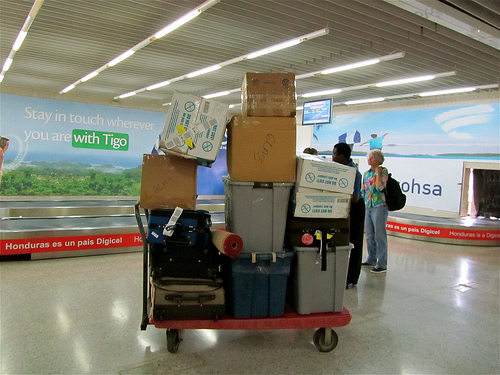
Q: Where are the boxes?
A: On the luggage cart.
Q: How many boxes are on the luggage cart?
A: 6.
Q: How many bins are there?
A: 3.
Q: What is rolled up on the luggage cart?
A: Rug.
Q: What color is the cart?
A: Red.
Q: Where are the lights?
A: On the ceiling.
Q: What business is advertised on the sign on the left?
A: Tigo.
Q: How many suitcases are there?
A: 3.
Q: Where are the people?
A: Behind the cart.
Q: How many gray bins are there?
A: 2.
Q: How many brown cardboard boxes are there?
A: 3.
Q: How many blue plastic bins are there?
A: 1.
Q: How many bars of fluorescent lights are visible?
A: 6.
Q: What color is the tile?
A: Gray.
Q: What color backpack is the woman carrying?
A: Black.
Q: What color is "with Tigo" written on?
A: Green.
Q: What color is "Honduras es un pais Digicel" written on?
A: Red.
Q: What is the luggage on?
A: Dolly.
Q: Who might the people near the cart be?
A: Customers.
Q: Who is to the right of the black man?
A: White woman.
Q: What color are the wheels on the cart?
A: Black and gray.